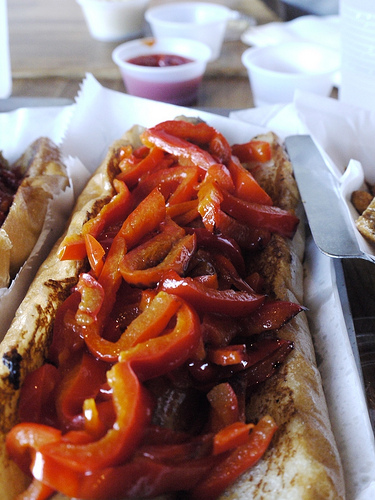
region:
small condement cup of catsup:
[107, 31, 208, 104]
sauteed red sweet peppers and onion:
[125, 117, 300, 490]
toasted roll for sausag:
[1, 200, 51, 430]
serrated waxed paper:
[0, 68, 103, 316]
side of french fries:
[342, 146, 374, 247]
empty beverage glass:
[239, 37, 346, 104]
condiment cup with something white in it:
[73, 0, 158, 42]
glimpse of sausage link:
[145, 363, 197, 498]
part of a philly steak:
[0, 70, 118, 266]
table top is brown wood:
[10, 18, 116, 99]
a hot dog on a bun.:
[25, 103, 245, 498]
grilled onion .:
[18, 355, 152, 467]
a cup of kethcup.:
[96, 20, 216, 112]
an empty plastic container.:
[232, 31, 347, 112]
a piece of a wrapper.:
[88, 85, 125, 127]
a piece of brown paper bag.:
[2, 120, 77, 281]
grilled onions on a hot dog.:
[83, 127, 234, 317]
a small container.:
[65, 0, 149, 49]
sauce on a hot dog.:
[152, 312, 262, 418]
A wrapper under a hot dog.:
[26, 46, 267, 196]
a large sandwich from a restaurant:
[2, 105, 347, 498]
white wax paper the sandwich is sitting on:
[71, 75, 132, 126]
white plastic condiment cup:
[239, 43, 344, 103]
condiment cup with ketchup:
[111, 34, 214, 106]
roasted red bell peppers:
[121, 134, 252, 494]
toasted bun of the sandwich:
[276, 375, 316, 498]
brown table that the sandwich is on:
[23, 33, 81, 83]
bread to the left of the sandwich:
[3, 134, 58, 243]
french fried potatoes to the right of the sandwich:
[339, 156, 373, 267]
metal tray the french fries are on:
[283, 129, 361, 273]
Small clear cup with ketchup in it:
[113, 35, 210, 104]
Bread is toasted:
[212, 127, 345, 498]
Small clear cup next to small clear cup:
[236, 41, 336, 102]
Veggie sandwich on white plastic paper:
[0, 117, 346, 498]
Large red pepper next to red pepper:
[28, 296, 197, 493]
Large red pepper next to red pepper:
[83, 185, 166, 327]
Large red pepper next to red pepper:
[196, 409, 284, 494]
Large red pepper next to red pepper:
[158, 267, 268, 313]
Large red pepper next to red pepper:
[197, 156, 231, 229]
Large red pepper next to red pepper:
[53, 168, 131, 263]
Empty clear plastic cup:
[144, 2, 235, 40]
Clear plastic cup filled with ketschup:
[114, 35, 205, 91]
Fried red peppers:
[136, 151, 235, 361]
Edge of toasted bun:
[280, 385, 330, 487]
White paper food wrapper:
[65, 69, 105, 134]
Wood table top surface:
[25, 5, 81, 94]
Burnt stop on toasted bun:
[2, 347, 22, 387]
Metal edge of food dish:
[299, 147, 341, 239]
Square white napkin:
[265, 18, 329, 39]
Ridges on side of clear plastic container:
[345, 3, 368, 99]